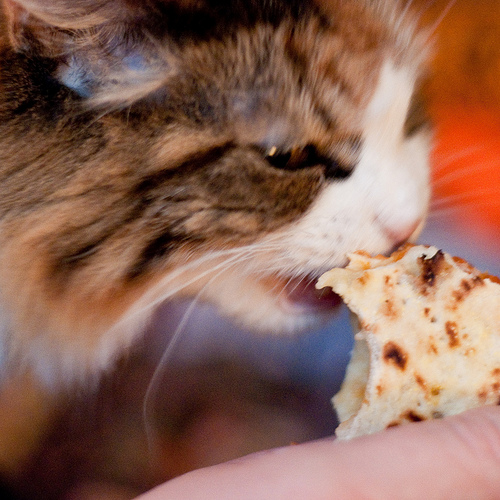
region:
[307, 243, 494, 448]
a piece of food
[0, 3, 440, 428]
the cat is biting a piece of food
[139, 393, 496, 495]
a person's hand holding a piece of food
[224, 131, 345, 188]
the cat's right eye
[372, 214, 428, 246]
the cat has a light pink nose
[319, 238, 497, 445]
a bit piece of tortilla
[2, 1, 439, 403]
the head of a cat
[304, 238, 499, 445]
a cheese crisp that the cat is biting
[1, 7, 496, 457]
the cat is smelling a piece of people food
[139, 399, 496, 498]
part of a person's hand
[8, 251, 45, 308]
Patch of long hair on animal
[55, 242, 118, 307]
Patch of long hair on animal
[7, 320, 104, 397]
Patch of long hair on animal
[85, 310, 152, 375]
Patch of long hair on animal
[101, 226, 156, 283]
Patch of long hair on animal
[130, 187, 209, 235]
Patch of long hair on animal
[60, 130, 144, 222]
Patch of long hair on animal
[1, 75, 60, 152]
Patch of long hair on animal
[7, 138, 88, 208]
Patch of long hair on animal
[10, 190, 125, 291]
Patch of long hair on animal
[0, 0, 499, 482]
cat munching burrito bite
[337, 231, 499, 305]
stuffing of the burrito [or flatbread, or pita. impossible to tell]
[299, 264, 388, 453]
munch marks, human or animal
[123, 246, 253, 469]
one bent white whisker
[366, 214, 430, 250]
a moving pink nose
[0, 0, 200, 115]
fuzz in the ear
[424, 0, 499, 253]
orange in the background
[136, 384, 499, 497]
large finger, all the way up front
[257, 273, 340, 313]
pink lips, pink interior mouth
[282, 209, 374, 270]
the little holes wherefrom the whiskers come out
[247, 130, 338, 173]
Eye of hungry cat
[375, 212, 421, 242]
Nose of hungry cat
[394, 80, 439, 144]
Eye of hungry cat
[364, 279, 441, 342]
Meal for hungry cat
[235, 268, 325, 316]
Mouth of hungry cat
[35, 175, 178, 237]
Black whisker of cat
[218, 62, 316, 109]
striped fur of cat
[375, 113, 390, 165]
White fur on cat's face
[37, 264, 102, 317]
Striped fur on cat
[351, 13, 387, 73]
Pat of striped fur on cat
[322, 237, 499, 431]
a brown piece of bread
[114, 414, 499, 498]
a pink finger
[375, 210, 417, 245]
a cat's pink nose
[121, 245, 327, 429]
a cat's white whiskers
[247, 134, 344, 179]
a cat's orange eye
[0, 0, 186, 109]
a cat's ear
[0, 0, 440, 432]
a cat nibbling on some bread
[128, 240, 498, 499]
a person holding a piece of bread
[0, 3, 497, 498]
a person feeding a cat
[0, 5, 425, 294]
a brown cat